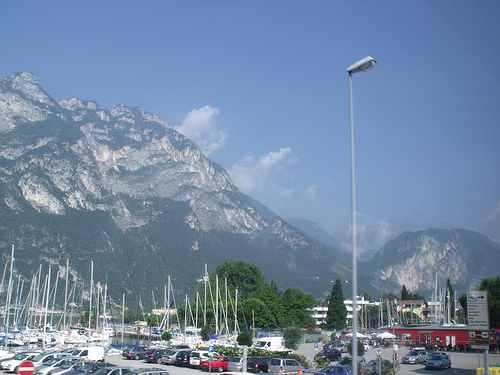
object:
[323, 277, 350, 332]
tree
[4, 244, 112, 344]
boats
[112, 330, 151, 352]
water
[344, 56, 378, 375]
light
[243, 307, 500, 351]
street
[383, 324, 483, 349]
building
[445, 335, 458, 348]
doors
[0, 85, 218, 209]
mountains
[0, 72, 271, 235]
snow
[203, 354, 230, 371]
car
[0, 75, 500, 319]
mountain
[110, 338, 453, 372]
cars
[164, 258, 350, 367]
trees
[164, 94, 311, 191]
clouds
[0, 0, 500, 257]
sky